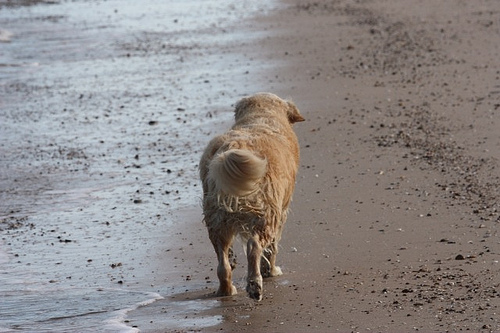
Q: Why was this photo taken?
A: To capture the dog on the beach.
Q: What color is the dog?
A: The dog is brown.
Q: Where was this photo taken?
A: On a beach.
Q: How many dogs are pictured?
A: Just 1.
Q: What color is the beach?
A: The sand is brown.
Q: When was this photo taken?
A: During the day.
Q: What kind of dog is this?
A: A golden reciever.